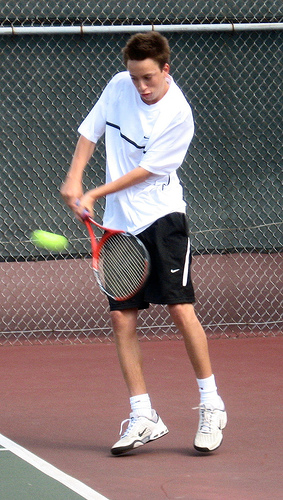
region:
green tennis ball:
[31, 227, 70, 254]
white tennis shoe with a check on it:
[108, 407, 172, 455]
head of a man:
[121, 30, 174, 102]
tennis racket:
[68, 196, 148, 303]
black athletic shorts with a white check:
[100, 210, 196, 312]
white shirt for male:
[76, 71, 194, 236]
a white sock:
[195, 373, 225, 407]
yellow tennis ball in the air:
[28, 223, 72, 256]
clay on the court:
[127, 464, 187, 491]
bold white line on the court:
[22, 458, 74, 485]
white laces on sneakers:
[108, 414, 139, 436]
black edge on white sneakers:
[109, 445, 134, 453]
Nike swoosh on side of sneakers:
[134, 425, 153, 437]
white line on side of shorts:
[182, 230, 196, 285]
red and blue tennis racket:
[62, 200, 160, 296]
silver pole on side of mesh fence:
[185, 11, 251, 44]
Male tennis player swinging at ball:
[60, 30, 227, 455]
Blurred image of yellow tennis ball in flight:
[30, 228, 69, 251]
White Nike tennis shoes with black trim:
[110, 394, 227, 455]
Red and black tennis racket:
[73, 197, 151, 302]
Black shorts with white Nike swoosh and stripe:
[102, 211, 195, 311]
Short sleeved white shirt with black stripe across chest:
[77, 70, 187, 236]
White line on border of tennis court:
[0, 432, 110, 498]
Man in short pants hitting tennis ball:
[60, 31, 228, 456]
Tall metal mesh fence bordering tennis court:
[1, 0, 281, 344]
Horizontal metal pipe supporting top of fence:
[0, 21, 282, 34]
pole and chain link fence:
[1, 1, 281, 343]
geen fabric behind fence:
[0, 1, 282, 343]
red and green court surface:
[0, 328, 280, 499]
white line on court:
[0, 431, 107, 498]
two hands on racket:
[60, 188, 151, 299]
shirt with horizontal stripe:
[76, 71, 193, 231]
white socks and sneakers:
[111, 374, 227, 454]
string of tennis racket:
[97, 234, 143, 295]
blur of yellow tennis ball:
[31, 228, 66, 248]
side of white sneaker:
[110, 411, 168, 454]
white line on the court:
[23, 433, 52, 484]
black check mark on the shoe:
[133, 425, 150, 439]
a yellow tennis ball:
[38, 230, 71, 253]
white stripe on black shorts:
[180, 244, 193, 280]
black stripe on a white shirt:
[116, 119, 134, 151]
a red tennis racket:
[84, 209, 130, 284]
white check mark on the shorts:
[169, 257, 184, 279]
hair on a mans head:
[118, 37, 177, 104]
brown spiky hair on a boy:
[123, 30, 169, 72]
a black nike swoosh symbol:
[137, 426, 149, 436]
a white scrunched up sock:
[128, 393, 152, 416]